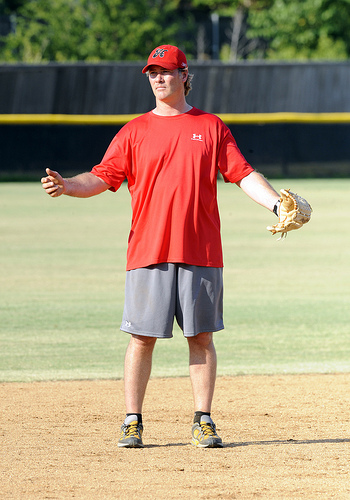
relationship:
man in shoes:
[36, 21, 313, 455] [117, 411, 227, 452]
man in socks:
[36, 21, 313, 455] [123, 412, 215, 424]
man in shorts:
[36, 21, 313, 455] [119, 243, 230, 342]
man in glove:
[36, 21, 313, 455] [266, 180, 316, 245]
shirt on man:
[89, 107, 236, 276] [36, 21, 313, 455]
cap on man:
[136, 41, 189, 70] [36, 21, 313, 455]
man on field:
[36, 21, 313, 455] [2, 180, 345, 492]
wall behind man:
[1, 61, 348, 185] [36, 21, 313, 455]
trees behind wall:
[0, 1, 349, 57] [1, 61, 348, 185]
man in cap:
[36, 21, 313, 455] [136, 41, 189, 70]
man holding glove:
[36, 21, 313, 455] [266, 180, 316, 245]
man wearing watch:
[36, 21, 313, 455] [267, 197, 282, 214]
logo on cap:
[149, 45, 170, 59] [136, 41, 189, 70]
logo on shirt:
[181, 130, 210, 148] [89, 107, 236, 276]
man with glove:
[36, 21, 313, 455] [266, 180, 316, 245]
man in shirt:
[36, 21, 313, 455] [89, 107, 236, 276]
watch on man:
[267, 197, 282, 214] [36, 21, 313, 455]